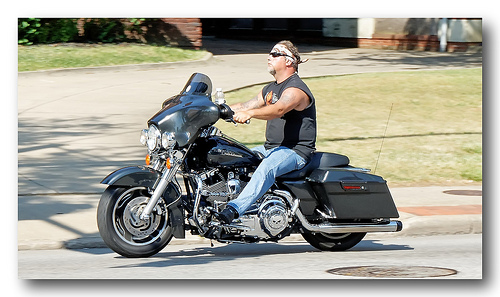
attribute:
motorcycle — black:
[128, 114, 379, 243]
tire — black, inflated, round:
[101, 191, 113, 216]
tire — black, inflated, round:
[315, 239, 344, 247]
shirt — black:
[283, 114, 307, 144]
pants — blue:
[275, 155, 298, 169]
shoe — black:
[225, 206, 235, 216]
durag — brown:
[276, 44, 284, 54]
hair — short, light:
[283, 38, 294, 48]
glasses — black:
[272, 52, 280, 59]